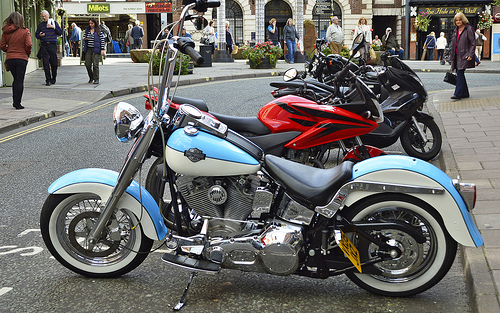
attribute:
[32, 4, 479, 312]
motorcycle — white, BLUE, red, black, light blue, street motorcycle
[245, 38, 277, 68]
flowers — planted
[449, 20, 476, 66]
jacket — brown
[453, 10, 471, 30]
hair — blonde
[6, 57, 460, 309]
ground — asphalt, gray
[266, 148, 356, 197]
seat — black, gray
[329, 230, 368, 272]
license plate — yellow, black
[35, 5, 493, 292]
bike — blue, white, black, red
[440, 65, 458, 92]
handbag — ladies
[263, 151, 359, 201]
seat — black, motorcycle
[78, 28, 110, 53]
shirt — blue, white, striped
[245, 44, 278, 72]
planter — flower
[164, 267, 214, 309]
kickstand — metal, silver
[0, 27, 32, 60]
jacket — brown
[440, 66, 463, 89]
pocketbook — black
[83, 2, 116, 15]
sign — green, yellow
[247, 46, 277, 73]
pot — black, large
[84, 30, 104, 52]
vest — blue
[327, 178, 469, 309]
tire — rear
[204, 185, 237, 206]
gas tank — blue, white